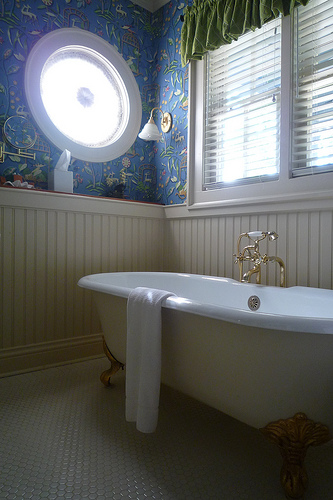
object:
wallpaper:
[29, 5, 110, 26]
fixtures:
[233, 230, 285, 289]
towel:
[121, 289, 165, 439]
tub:
[76, 272, 333, 433]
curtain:
[179, 0, 302, 63]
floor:
[5, 412, 116, 492]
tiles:
[44, 430, 54, 441]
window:
[37, 43, 129, 149]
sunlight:
[51, 61, 115, 135]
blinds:
[201, 19, 278, 185]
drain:
[246, 295, 261, 314]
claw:
[98, 355, 121, 388]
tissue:
[55, 147, 71, 171]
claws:
[264, 421, 321, 500]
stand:
[99, 357, 121, 388]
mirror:
[2, 112, 38, 150]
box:
[48, 168, 74, 193]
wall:
[153, 48, 178, 91]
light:
[135, 108, 173, 146]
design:
[127, 41, 152, 66]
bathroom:
[8, 6, 330, 494]